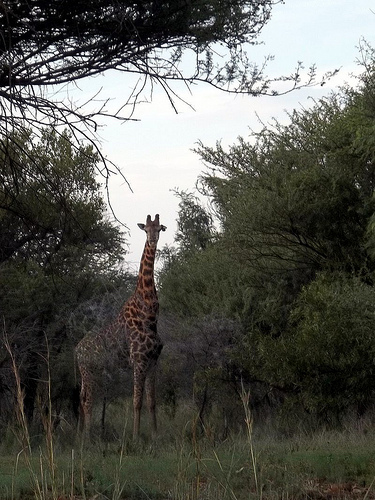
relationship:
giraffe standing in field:
[72, 214, 165, 455] [2, 403, 373, 500]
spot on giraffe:
[143, 279, 153, 287] [72, 214, 165, 455]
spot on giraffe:
[133, 310, 145, 319] [72, 214, 165, 455]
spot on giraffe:
[146, 254, 158, 263] [72, 214, 165, 455]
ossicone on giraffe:
[154, 213, 163, 223] [72, 214, 165, 455]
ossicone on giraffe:
[146, 215, 152, 225] [72, 214, 165, 455]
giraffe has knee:
[72, 214, 165, 455] [132, 405, 142, 413]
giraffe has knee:
[72, 214, 165, 455] [146, 401, 156, 410]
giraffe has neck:
[72, 214, 165, 455] [140, 244, 157, 289]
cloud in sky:
[278, 65, 373, 101] [3, 4, 374, 267]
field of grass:
[2, 403, 373, 500] [183, 414, 244, 498]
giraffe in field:
[72, 214, 165, 455] [2, 403, 373, 500]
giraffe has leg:
[72, 214, 165, 455] [132, 367, 146, 450]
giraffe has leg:
[72, 214, 165, 455] [144, 369, 158, 442]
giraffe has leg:
[72, 214, 165, 455] [79, 382, 92, 438]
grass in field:
[183, 414, 244, 498] [2, 403, 373, 500]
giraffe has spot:
[72, 214, 165, 455] [143, 279, 153, 287]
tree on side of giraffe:
[298, 61, 374, 415] [72, 214, 165, 455]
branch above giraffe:
[2, 56, 139, 229] [72, 214, 165, 455]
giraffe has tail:
[72, 214, 165, 455] [69, 353, 81, 415]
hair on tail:
[69, 387, 81, 412] [69, 353, 81, 415]